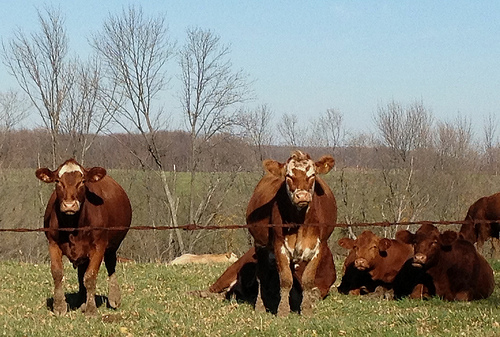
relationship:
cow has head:
[13, 141, 498, 315] [40, 162, 104, 212]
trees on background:
[7, 4, 498, 242] [14, 60, 476, 176]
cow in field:
[13, 141, 498, 315] [0, 165, 498, 337]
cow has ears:
[13, 141, 498, 315] [36, 166, 107, 185]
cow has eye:
[13, 141, 498, 315] [53, 178, 85, 189]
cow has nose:
[13, 141, 498, 315] [54, 197, 82, 213]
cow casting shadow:
[13, 141, 498, 315] [233, 255, 311, 315]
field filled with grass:
[1, 239, 484, 329] [5, 259, 498, 329]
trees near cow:
[7, 4, 498, 242] [25, 155, 149, 320]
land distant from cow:
[6, 118, 484, 189] [13, 141, 498, 315]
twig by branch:
[182, 188, 215, 229] [190, 163, 250, 243]